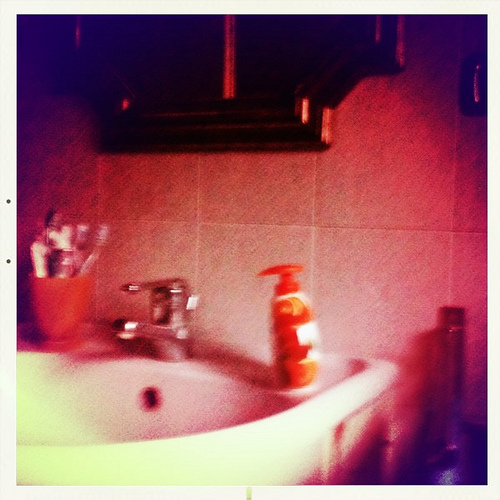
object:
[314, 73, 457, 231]
white tile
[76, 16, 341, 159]
mirror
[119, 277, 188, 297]
handle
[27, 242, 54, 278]
toothpaste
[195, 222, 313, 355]
tile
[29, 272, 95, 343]
cup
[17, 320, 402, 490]
wash basin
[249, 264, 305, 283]
spout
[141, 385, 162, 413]
drain hole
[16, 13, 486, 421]
wall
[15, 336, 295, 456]
sink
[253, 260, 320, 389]
bottle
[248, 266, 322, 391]
soap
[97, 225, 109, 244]
bristles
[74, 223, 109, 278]
toothbrush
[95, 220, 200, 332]
tile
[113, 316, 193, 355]
spout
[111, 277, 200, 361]
bathroom faucet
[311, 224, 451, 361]
tile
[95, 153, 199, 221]
tile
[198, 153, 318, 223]
tile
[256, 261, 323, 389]
dispenser